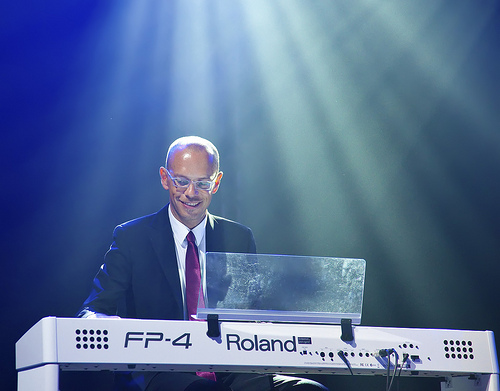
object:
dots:
[442, 339, 474, 360]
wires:
[377, 350, 410, 391]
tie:
[183, 230, 216, 384]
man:
[77, 134, 325, 390]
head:
[158, 136, 223, 222]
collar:
[167, 203, 208, 246]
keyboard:
[14, 314, 499, 376]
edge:
[205, 313, 355, 341]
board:
[14, 315, 499, 375]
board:
[196, 251, 366, 325]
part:
[303, 251, 318, 278]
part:
[387, 338, 409, 360]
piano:
[17, 316, 500, 390]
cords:
[338, 348, 410, 377]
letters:
[123, 331, 192, 350]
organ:
[14, 315, 500, 390]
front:
[57, 328, 491, 375]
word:
[226, 333, 297, 352]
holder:
[190, 251, 366, 341]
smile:
[178, 199, 203, 210]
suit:
[77, 202, 261, 391]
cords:
[155, 367, 240, 373]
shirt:
[168, 203, 208, 321]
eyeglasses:
[166, 168, 218, 191]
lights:
[85, 0, 494, 325]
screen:
[189, 251, 366, 327]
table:
[14, 315, 500, 391]